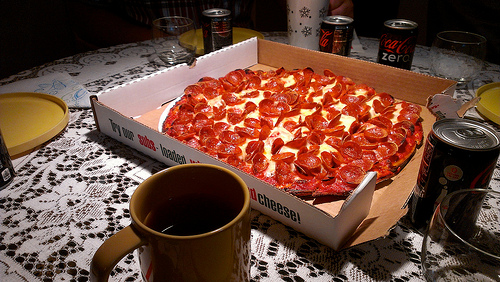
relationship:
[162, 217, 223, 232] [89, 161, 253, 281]
liquid in mug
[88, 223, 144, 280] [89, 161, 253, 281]
handle of mug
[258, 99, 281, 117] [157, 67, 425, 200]
pepperoni on pizza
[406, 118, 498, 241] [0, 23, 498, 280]
can on table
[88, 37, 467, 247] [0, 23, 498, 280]
box on table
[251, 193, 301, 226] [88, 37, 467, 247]
lettering on box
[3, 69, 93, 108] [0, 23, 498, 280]
napkin on table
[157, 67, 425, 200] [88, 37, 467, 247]
pizza in box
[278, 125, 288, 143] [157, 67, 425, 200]
cheese on pizza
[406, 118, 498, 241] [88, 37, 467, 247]
can by box